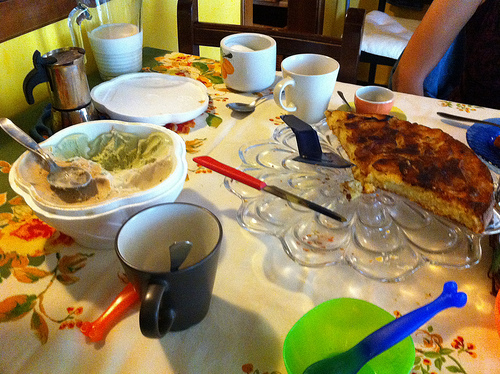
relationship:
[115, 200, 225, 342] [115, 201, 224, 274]
cup with white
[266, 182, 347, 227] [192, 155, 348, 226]
dirty red knife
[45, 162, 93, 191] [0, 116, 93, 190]
dirty silver spoon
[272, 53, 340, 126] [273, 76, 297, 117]
cup with handle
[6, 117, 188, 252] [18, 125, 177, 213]
container filled with food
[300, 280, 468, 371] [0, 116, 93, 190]
blue plastic spoon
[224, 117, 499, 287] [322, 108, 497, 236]
glass plate with food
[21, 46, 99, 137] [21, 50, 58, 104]
container with handle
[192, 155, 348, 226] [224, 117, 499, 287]
knife on plate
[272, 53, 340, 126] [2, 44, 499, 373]
mug on table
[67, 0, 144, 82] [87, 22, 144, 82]
pitcher of milk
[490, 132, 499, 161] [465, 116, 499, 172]
tart on plate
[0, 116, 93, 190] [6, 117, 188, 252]
spoon in bowl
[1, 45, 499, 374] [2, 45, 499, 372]
floral pattern on tablecloth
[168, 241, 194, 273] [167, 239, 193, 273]
handle of spoon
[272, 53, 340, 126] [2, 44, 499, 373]
coffee cup on table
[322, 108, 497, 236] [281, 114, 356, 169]
cake and pie knife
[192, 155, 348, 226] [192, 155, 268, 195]
knife with handle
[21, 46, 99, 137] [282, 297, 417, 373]
container in green bowl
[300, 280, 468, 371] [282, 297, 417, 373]
plastic spoon in green bowl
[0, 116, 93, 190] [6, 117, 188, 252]
steel spoon in a white container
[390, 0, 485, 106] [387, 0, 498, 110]
arm of a person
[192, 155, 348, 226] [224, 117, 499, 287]
knife on glass tray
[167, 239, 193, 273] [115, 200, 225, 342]
spoon in cup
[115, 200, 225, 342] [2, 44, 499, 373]
coffee cup on table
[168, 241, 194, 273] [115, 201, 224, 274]
utensil handle on cup rim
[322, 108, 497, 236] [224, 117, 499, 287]
partial cake on stand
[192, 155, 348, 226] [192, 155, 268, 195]
knife with red handle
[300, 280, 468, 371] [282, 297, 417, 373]
plastic utensil in bowl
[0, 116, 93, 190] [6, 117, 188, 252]
spoon in white bowl